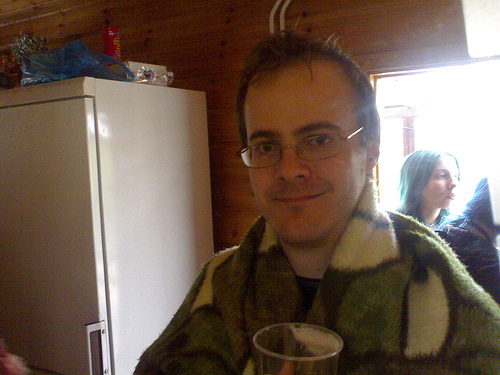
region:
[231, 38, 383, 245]
face of a man with glasses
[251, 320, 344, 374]
top half of a cup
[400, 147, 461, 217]
the face of a woman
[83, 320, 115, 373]
metal handle on a fridge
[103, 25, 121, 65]
red packaged goods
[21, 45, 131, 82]
a blue plastic bag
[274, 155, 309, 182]
nose of a white man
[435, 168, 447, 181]
a woman's right eye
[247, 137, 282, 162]
a man's right eye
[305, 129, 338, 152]
a man's left eye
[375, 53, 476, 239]
light coming in through window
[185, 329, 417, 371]
man holding coffee mug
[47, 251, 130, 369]
handle to the refrigerator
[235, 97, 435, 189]
man wearing glasses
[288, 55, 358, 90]
piece of hair on forehead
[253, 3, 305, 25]
cords attached to wall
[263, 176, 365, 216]
man is smiling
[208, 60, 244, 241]
wood on the walls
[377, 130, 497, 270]
light reflections on the woman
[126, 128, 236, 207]
shadow on refrigerator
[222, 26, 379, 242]
man is wearing pair of glasses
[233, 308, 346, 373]
man s holding a drink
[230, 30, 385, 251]
man is happy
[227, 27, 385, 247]
man is smiling with his mouth closed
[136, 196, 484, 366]
man is wearing a blanket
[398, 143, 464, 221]
woman looking to the right of picture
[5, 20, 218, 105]
fridge has items on top of it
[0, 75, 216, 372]
fridge is white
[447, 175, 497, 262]
person is wearing a necklace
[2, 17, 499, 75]
wall of room is made of wood and brown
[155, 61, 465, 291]
the guy with an eyeglass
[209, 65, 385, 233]
the guy with an eyeglass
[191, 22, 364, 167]
the guy with an eyeglass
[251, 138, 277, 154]
right eye of a man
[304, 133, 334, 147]
left eye of a man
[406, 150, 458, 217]
head of a young woman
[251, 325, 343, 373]
top of a plastic cup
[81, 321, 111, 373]
metal handle on a refridgerator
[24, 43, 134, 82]
light blue plastic bag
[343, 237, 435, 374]
green and white patterned blanket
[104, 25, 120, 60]
red box with yellow lettering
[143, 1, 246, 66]
wooden wall paneling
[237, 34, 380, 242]
the face of a young man